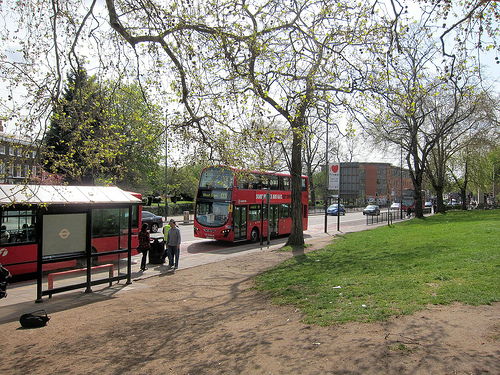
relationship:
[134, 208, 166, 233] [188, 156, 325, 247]
dark car across street from bus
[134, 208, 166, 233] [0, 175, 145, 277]
dark car across street from bus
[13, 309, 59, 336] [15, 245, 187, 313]
backpack near sidewalk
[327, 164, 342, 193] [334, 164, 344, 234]
banner on pole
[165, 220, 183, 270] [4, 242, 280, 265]
man walking down sidewalk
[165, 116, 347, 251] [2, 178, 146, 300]
bus stopped at stop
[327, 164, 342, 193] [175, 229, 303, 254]
banner on sidewalk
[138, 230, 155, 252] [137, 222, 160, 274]
coat on woman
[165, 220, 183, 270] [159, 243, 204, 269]
man wearing jeans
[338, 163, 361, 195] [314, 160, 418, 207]
windows are on building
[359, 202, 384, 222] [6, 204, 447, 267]
car driving on road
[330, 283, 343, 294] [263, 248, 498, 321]
trash lying ground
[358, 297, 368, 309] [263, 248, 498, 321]
trash lying ground